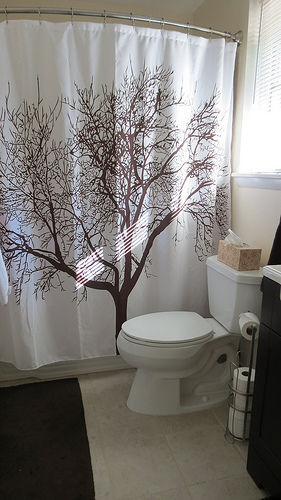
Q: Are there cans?
A: No, there are no cans.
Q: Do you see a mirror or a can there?
A: No, there are no cans or mirrors.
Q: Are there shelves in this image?
A: No, there are no shelves.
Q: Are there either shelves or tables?
A: No, there are no shelves or tables.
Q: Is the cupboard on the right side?
A: Yes, the cupboard is on the right of the image.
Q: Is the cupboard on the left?
A: No, the cupboard is on the right of the image.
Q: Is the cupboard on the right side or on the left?
A: The cupboard is on the right of the image.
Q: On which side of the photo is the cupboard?
A: The cupboard is on the right of the image.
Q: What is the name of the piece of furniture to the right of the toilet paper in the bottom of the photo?
A: The piece of furniture is a cupboard.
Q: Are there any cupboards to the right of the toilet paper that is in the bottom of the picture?
A: Yes, there is a cupboard to the right of the toilet paper.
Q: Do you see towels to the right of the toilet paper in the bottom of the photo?
A: No, there is a cupboard to the right of the toilet paper.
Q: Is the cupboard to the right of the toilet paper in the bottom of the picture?
A: Yes, the cupboard is to the right of the toilet paper.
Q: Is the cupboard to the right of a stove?
A: No, the cupboard is to the right of the toilet paper.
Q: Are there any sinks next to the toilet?
A: No, there is a cupboard next to the toilet.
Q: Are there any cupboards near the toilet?
A: Yes, there is a cupboard near the toilet.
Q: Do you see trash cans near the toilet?
A: No, there is a cupboard near the toilet.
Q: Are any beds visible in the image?
A: No, there are no beds.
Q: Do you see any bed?
A: No, there are no beds.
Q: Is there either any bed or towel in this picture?
A: No, there are no beds or towels.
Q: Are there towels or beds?
A: No, there are no beds or towels.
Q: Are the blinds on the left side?
A: No, the blinds are on the right of the image.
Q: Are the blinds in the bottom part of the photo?
A: No, the blinds are in the top of the image.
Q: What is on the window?
A: The blinds are on the window.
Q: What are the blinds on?
A: The blinds are on the window.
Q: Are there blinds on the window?
A: Yes, there are blinds on the window.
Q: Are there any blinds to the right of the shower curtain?
A: Yes, there are blinds to the right of the shower curtain.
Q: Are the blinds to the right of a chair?
A: No, the blinds are to the right of the shower curtain.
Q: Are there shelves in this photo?
A: No, there are no shelves.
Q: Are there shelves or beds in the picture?
A: No, there are no shelves or beds.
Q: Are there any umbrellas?
A: No, there are no umbrellas.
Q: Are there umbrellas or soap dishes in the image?
A: No, there are no umbrellas or soap dishes.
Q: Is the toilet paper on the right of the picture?
A: Yes, the toilet paper is on the right of the image.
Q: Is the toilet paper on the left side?
A: No, the toilet paper is on the right of the image.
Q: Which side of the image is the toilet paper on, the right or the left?
A: The toilet paper is on the right of the image.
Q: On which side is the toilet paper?
A: The toilet paper is on the right of the image.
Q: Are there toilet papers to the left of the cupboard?
A: Yes, there is a toilet paper to the left of the cupboard.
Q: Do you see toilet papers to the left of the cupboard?
A: Yes, there is a toilet paper to the left of the cupboard.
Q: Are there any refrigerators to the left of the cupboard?
A: No, there is a toilet paper to the left of the cupboard.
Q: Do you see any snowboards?
A: No, there are no snowboards.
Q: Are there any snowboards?
A: No, there are no snowboards.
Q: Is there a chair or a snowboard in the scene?
A: No, there are no snowboards or chairs.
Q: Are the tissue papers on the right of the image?
A: Yes, the tissue papers are on the right of the image.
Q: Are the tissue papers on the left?
A: No, the tissue papers are on the right of the image.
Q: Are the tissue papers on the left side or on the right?
A: The tissue papers are on the right of the image.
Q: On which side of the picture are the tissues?
A: The tissues are on the right of the image.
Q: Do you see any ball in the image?
A: No, there are no balls.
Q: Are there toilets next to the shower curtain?
A: Yes, there is a toilet next to the shower curtain.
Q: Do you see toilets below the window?
A: Yes, there is a toilet below the window.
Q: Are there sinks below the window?
A: No, there is a toilet below the window.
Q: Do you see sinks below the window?
A: No, there is a toilet below the window.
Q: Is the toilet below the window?
A: Yes, the toilet is below the window.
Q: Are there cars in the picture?
A: No, there are no cars.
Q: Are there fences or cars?
A: No, there are no cars or fences.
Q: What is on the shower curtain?
A: The tree is on the shower curtain.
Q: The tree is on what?
A: The tree is on the shower curtain.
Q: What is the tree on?
A: The tree is on the shower curtain.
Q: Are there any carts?
A: No, there are no carts.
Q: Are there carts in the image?
A: No, there are no carts.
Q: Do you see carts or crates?
A: No, there are no carts or crates.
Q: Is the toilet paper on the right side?
A: Yes, the toilet paper is on the right of the image.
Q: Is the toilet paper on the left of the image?
A: No, the toilet paper is on the right of the image.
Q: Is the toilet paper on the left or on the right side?
A: The toilet paper is on the right of the image.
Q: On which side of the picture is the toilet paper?
A: The toilet paper is on the right of the image.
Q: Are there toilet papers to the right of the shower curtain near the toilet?
A: Yes, there is a toilet paper to the right of the shower curtain.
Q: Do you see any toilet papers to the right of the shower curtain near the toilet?
A: Yes, there is a toilet paper to the right of the shower curtain.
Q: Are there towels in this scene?
A: No, there are no towels.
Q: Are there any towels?
A: No, there are no towels.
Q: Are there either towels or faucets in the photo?
A: No, there are no towels or faucets.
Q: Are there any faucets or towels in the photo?
A: No, there are no towels or faucets.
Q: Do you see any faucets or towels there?
A: No, there are no towels or faucets.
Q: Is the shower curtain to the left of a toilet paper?
A: Yes, the shower curtain is to the left of a toilet paper.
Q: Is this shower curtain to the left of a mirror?
A: No, the shower curtain is to the left of a toilet paper.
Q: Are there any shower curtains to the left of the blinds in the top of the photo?
A: Yes, there is a shower curtain to the left of the blinds.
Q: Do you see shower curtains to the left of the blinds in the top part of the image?
A: Yes, there is a shower curtain to the left of the blinds.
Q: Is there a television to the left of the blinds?
A: No, there is a shower curtain to the left of the blinds.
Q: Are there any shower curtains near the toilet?
A: Yes, there is a shower curtain near the toilet.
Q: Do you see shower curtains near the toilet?
A: Yes, there is a shower curtain near the toilet.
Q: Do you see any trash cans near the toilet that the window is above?
A: No, there is a shower curtain near the toilet.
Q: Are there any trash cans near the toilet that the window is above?
A: No, there is a shower curtain near the toilet.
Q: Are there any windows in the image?
A: Yes, there is a window.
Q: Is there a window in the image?
A: Yes, there is a window.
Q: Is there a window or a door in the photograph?
A: Yes, there is a window.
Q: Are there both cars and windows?
A: No, there is a window but no cars.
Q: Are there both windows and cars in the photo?
A: No, there is a window but no cars.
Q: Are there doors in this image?
A: No, there are no doors.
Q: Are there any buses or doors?
A: No, there are no doors or buses.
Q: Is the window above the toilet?
A: Yes, the window is above the toilet.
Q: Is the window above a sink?
A: No, the window is above the toilet.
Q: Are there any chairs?
A: No, there are no chairs.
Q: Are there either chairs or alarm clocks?
A: No, there are no chairs or alarm clocks.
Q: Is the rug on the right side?
A: No, the rug is on the left of the image.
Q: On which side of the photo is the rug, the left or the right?
A: The rug is on the left of the image.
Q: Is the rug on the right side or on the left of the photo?
A: The rug is on the left of the image.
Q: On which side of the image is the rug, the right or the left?
A: The rug is on the left of the image.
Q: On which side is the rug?
A: The rug is on the left of the image.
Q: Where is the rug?
A: The rug is on the floor.